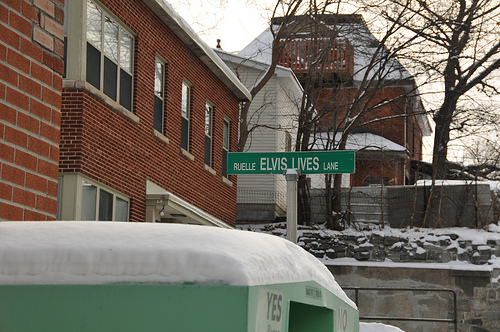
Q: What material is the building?
A: Brick.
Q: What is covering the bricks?
A: Snow.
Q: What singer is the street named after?
A: Elvis.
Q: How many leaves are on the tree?
A: None.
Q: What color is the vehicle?
A: Green.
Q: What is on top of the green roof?
A: Snow.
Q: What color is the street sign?
A: Green and white.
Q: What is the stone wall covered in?
A: Snow.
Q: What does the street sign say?
A: Elvis Lives.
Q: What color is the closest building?
A: Red brick.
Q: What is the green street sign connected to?
A: A pole.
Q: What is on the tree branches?
A: Snow.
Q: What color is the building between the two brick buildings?
A: White.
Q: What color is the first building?
A: Red.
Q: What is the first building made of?
A: Red brick.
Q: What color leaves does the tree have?
A: None.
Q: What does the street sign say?
A: Ruelle Elvis Lives Lane.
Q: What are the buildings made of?
A: Brick.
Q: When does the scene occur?
A: Daytime.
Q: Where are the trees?
A: To the right.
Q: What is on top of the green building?
A: Snow.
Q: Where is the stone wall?
A: Behind the green building.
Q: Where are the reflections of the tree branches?
A: In the building's windows.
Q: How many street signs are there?
A: One.